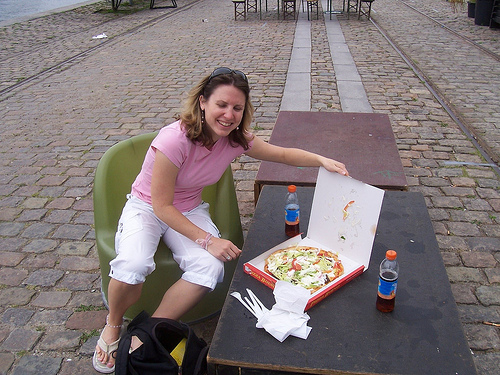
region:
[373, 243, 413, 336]
bottle with an orange cap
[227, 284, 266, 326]
white plastic cutlery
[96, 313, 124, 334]
ankle bacelet on a person's ankle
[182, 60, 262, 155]
woman with sunglases on her hair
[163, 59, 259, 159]
woman with medium length brown hair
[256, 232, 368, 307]
pizza inside a pizza box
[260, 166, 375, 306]
open pizza box with a drink next to it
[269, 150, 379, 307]
open pizza box on a table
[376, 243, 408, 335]
a bottle with a drink inside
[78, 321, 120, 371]
cream flip flop on a foot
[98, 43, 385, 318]
a woman at a table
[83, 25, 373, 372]
a woman sitting in a chiar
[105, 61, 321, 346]
a woman sitting in a green chair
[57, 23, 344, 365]
a woman sitting on a plastic chair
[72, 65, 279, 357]
a woman sitting on a green plastic chair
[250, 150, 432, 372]
a pizza on the table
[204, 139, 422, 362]
a small pizza in a box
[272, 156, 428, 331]
a cooked pizza on table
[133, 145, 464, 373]
a baked pizza on the table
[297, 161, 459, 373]
two bottles of drink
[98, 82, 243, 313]
a lady in a pink shirt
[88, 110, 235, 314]
a green chair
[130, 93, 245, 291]
a lady sitting in a chair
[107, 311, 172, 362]
a black bag next to the lady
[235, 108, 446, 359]
two tables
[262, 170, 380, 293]
a box of pizza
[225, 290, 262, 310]
plastic utensils on the table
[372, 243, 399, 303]
a bottle on the table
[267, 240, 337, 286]
the pizza in the box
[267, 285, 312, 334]
napkins on the table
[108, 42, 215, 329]
woman sitting at table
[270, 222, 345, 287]
pizza in cardboard box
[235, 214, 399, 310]
cardboard box on table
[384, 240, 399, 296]
plastic bottle on table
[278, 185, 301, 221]
plastic bottle on table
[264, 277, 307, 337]
white napkins on table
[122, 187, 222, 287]
white pants on woman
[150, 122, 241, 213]
pink shirt on woman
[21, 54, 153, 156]
cobblestones on the road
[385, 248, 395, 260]
orange cap on bottle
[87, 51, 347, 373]
Woman sitting at a table.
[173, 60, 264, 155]
Woman smiling with her eyes closed.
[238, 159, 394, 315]
Pizza in a box on the table.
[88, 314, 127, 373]
Flip flops on the woman.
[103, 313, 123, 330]
Ankel bracelet on the woman.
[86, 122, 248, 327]
Woman in a green chair.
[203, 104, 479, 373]
Two tables lines up next to each other.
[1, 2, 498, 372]
Brick walkway where woman is sitting.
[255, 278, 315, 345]
Napkins on the table.